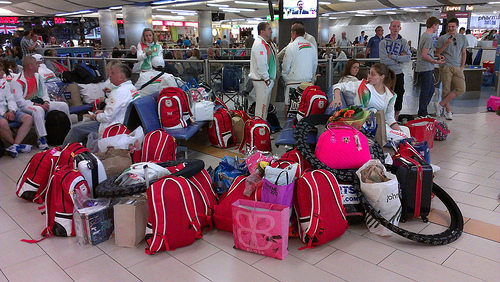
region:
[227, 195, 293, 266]
A pink gift back on the ground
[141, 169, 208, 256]
A red backpack on the floor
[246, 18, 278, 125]
A person standing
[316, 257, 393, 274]
Part of the floor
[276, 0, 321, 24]
A TV hanging on the wall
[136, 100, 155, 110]
Part of the blue chair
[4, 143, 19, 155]
The person's white shoe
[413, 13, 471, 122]
Two people talking to each other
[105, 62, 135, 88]
The head of the person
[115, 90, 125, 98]
Part of the white jacket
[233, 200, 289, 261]
Pink butterfly bag sitting on the front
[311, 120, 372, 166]
Neon pink bag sitting on top and to the right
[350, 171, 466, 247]
Bicyle wheel sitting to the right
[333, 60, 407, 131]
Woman looking over her shoulder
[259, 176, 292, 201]
Purple bag behind pink butterfly bag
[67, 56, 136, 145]
Older man sitting to the left in white jacket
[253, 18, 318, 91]
Three men talking in the background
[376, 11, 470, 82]
Three men in grey shirts on the right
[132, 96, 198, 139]
Blue seats in the sitting area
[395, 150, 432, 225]
Black suitcase trimmed in red to the right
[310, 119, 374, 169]
hot pink carry on bag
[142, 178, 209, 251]
red back pack with white trim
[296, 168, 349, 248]
red back pack with white trim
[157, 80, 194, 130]
red back pack with white trim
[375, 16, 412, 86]
boy wearing a grey sweatshirt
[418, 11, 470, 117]
toy boys wearing grey tee shirts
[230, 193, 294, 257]
hot pink gift bag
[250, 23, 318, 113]
two men wearing white jackets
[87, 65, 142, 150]
man sitting on blue chair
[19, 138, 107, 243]
group of three red back packs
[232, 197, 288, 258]
pink bag with a butterfly on it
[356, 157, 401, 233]
white bag with black lines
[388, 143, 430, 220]
black suitcase with red stripe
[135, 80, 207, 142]
blue plastic bench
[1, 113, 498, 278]
section of light tiled floor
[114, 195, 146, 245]
brown paper sack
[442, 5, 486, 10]
black sign with yellow words from lights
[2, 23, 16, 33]
blue and red flag on the wall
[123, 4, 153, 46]
large round white pillar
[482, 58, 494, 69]
red plastic tote behind the counter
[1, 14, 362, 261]
sports group preparing for group travel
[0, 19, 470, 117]
passengers preparing for travel at an airport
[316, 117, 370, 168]
bright pink carry on bag of a passenger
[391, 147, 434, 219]
black and red carry on baggage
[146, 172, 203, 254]
red carry on back pack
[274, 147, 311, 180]
red carry on back pack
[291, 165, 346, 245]
red carry on back pack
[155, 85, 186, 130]
red carry on back pack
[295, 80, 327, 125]
red carry on back pack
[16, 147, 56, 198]
red carry on back pack